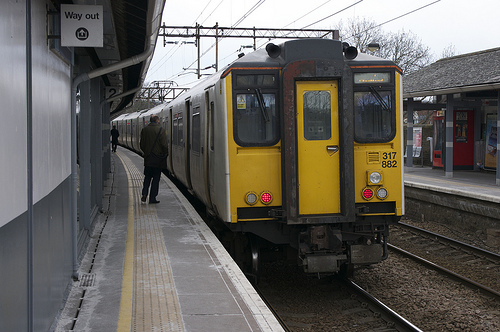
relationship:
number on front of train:
[380, 148, 397, 169] [154, 49, 414, 240]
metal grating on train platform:
[80, 269, 95, 289] [96, 212, 206, 330]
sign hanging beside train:
[57, 3, 104, 47] [164, 92, 389, 219]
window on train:
[189, 98, 204, 153] [164, 92, 389, 219]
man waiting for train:
[137, 114, 173, 213] [106, 35, 452, 287]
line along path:
[112, 150, 134, 330] [117, 150, 184, 330]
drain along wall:
[60, 210, 112, 330] [0, 8, 77, 330]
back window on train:
[221, 70, 282, 144] [130, 60, 408, 267]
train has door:
[164, 92, 389, 219] [296, 77, 339, 214]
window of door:
[302, 87, 333, 139] [293, 72, 347, 217]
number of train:
[380, 148, 397, 169] [112, 55, 443, 275]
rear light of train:
[366, 172, 386, 182] [171, 38, 409, 270]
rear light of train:
[358, 182, 377, 204] [171, 38, 409, 270]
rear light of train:
[375, 185, 388, 202] [171, 38, 409, 270]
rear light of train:
[259, 188, 273, 205] [171, 38, 409, 270]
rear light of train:
[245, 187, 259, 207] [171, 38, 409, 270]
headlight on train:
[368, 186, 373, 193] [164, 92, 389, 219]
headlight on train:
[375, 186, 389, 198] [164, 92, 389, 219]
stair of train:
[300, 248, 348, 278] [164, 92, 389, 219]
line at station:
[85, 192, 162, 327] [1, 1, 498, 330]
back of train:
[224, 43, 401, 226] [106, 35, 452, 287]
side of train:
[111, 70, 229, 222] [164, 92, 389, 219]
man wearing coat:
[140, 110, 172, 208] [140, 124, 170, 159]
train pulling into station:
[164, 92, 389, 219] [1, 1, 498, 330]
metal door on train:
[297, 78, 339, 217] [164, 92, 389, 219]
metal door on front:
[297, 78, 339, 217] [224, 57, 403, 227]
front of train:
[224, 57, 403, 227] [164, 92, 389, 219]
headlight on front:
[243, 187, 262, 207] [224, 57, 403, 227]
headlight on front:
[258, 187, 273, 204] [224, 57, 403, 227]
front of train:
[224, 57, 403, 227] [177, 28, 419, 294]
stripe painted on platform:
[114, 150, 134, 330] [50, 142, 285, 329]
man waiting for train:
[137, 114, 173, 213] [197, 33, 424, 280]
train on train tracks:
[164, 92, 389, 219] [344, 273, 406, 320]